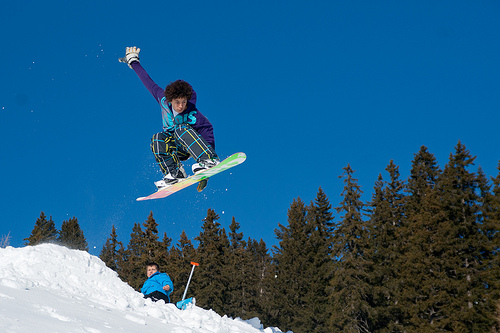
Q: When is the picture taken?
A: Daytime.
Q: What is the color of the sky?
A: Blue.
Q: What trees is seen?
A: Pine.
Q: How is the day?
A: Sunny.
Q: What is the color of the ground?
A: White.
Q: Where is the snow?
A: In the ground.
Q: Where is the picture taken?
A: At a ski slope.